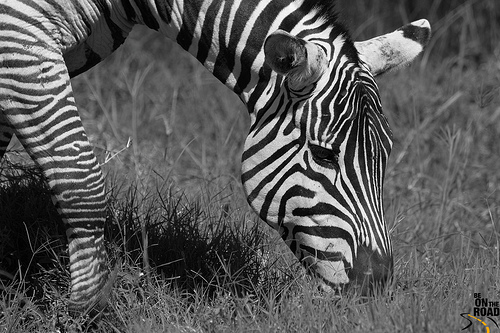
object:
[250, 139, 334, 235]
stripes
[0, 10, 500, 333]
ground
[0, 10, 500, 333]
grass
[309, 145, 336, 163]
eye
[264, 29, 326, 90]
ear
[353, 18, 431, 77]
ear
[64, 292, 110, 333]
feet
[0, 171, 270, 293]
shadow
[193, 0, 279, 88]
neck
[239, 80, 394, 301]
head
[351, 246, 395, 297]
nose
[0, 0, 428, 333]
zebra